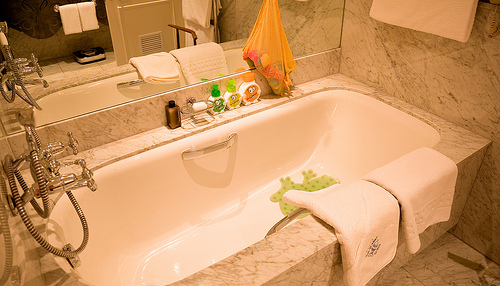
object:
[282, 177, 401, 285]
towel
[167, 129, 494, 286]
edge of tub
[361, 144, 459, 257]
towel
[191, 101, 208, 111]
soap dish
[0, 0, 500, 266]
wall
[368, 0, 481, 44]
towel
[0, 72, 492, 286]
bathtub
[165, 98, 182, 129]
bottle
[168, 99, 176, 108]
cap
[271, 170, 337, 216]
bath mat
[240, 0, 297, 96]
bag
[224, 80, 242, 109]
bottle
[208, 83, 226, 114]
bottle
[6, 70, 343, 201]
side of tub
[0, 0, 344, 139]
mirror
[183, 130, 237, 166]
handle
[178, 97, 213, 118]
soap tray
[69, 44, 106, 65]
reflection of scale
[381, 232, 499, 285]
floor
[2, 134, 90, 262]
hose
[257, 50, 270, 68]
bath toy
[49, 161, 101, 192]
faucet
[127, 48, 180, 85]
towel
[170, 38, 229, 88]
towel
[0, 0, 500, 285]
stone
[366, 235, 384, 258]
emblem